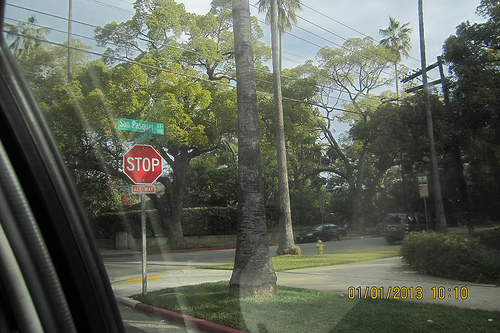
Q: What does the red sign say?
A: Stop.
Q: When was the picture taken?
A: 01/01/2013.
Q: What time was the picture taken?
A: 10:10.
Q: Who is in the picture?
A: No one.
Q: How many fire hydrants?
A: 1.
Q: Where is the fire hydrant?
A: Next to tree.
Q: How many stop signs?
A: 1.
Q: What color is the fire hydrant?
A: Yellow.